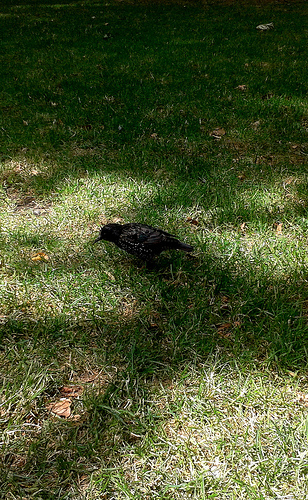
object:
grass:
[0, 0, 305, 496]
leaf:
[44, 397, 70, 419]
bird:
[91, 223, 195, 263]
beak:
[89, 236, 102, 246]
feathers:
[150, 233, 160, 237]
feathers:
[172, 245, 195, 247]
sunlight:
[189, 378, 308, 500]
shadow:
[1, 1, 304, 188]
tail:
[175, 241, 195, 252]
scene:
[6, 9, 304, 492]